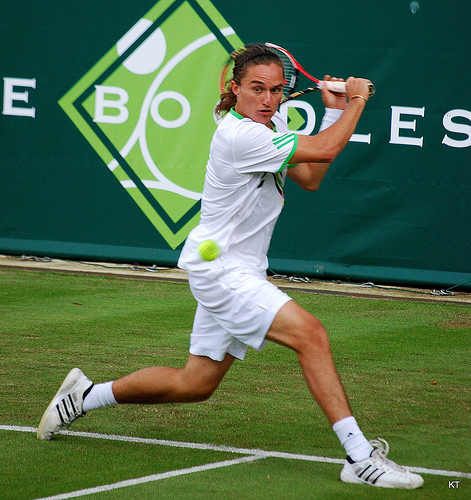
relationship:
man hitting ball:
[37, 46, 425, 488] [192, 235, 226, 266]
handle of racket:
[314, 77, 384, 100] [219, 36, 384, 119]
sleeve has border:
[224, 114, 299, 183] [280, 130, 303, 179]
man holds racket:
[37, 46, 425, 488] [219, 36, 384, 119]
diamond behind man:
[69, 3, 267, 233] [37, 46, 425, 488]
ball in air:
[192, 235, 226, 266] [155, 222, 176, 274]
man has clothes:
[178, 46, 335, 326] [182, 108, 306, 342]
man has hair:
[178, 46, 335, 326] [215, 49, 285, 83]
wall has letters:
[340, 18, 447, 78] [385, 92, 468, 158]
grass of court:
[80, 295, 126, 338] [8, 262, 462, 496]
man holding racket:
[178, 46, 335, 326] [219, 36, 384, 119]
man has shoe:
[178, 46, 335, 326] [343, 440, 427, 488]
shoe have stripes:
[343, 440, 427, 488] [52, 394, 84, 429]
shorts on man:
[181, 239, 292, 370] [178, 46, 335, 326]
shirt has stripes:
[182, 108, 306, 342] [52, 394, 84, 429]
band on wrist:
[346, 92, 370, 104] [341, 84, 370, 123]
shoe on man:
[343, 440, 427, 488] [37, 46, 425, 488]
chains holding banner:
[25, 248, 147, 276] [5, 25, 166, 271]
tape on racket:
[330, 80, 338, 93] [219, 36, 384, 119]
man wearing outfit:
[37, 46, 425, 488] [182, 108, 306, 342]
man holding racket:
[37, 46, 425, 488] [219, 36, 384, 119]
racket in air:
[219, 36, 384, 119] [155, 222, 176, 274]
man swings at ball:
[37, 46, 425, 488] [192, 235, 226, 266]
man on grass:
[37, 46, 425, 488] [80, 295, 126, 338]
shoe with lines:
[343, 440, 427, 495] [358, 459, 395, 494]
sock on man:
[81, 375, 122, 417] [178, 46, 335, 326]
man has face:
[178, 46, 335, 326] [237, 63, 288, 122]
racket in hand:
[219, 36, 384, 119] [334, 71, 368, 127]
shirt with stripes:
[209, 113, 285, 272] [52, 394, 84, 429]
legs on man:
[174, 271, 353, 434] [178, 46, 335, 326]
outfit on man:
[182, 108, 306, 342] [178, 46, 335, 326]